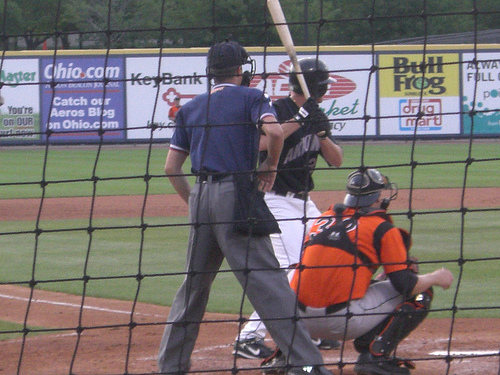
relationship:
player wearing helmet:
[235, 59, 345, 360] [292, 64, 338, 90]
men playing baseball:
[147, 42, 443, 374] [7, 137, 499, 371]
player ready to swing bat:
[235, 59, 345, 360] [268, 3, 324, 116]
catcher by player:
[304, 169, 446, 359] [235, 59, 345, 360]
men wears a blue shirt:
[154, 42, 333, 375] [167, 89, 277, 172]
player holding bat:
[235, 59, 345, 360] [268, 3, 324, 116]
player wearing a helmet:
[235, 59, 345, 360] [292, 64, 338, 90]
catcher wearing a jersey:
[304, 169, 446, 359] [296, 204, 411, 299]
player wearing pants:
[235, 59, 345, 360] [233, 187, 337, 338]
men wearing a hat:
[154, 42, 333, 375] [210, 46, 249, 74]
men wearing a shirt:
[154, 42, 333, 375] [167, 89, 277, 172]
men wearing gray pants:
[154, 42, 333, 375] [157, 175, 320, 372]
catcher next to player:
[304, 169, 446, 359] [235, 59, 345, 360]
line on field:
[7, 284, 165, 331] [2, 46, 498, 374]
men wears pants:
[154, 42, 333, 375] [157, 175, 320, 372]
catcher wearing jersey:
[304, 169, 446, 359] [296, 204, 411, 299]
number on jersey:
[308, 217, 356, 245] [296, 204, 411, 299]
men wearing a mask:
[154, 42, 333, 375] [237, 52, 256, 87]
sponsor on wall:
[42, 61, 123, 91] [7, 58, 496, 140]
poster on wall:
[129, 60, 376, 137] [7, 58, 496, 140]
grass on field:
[21, 142, 490, 183] [2, 46, 498, 374]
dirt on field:
[21, 191, 178, 222] [2, 46, 498, 374]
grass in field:
[21, 142, 490, 183] [2, 46, 498, 374]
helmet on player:
[292, 64, 338, 90] [235, 59, 345, 360]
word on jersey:
[288, 137, 319, 168] [268, 99, 331, 194]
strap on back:
[323, 217, 351, 241] [305, 210, 370, 307]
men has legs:
[154, 42, 333, 375] [160, 225, 320, 371]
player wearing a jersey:
[235, 59, 345, 360] [268, 99, 331, 194]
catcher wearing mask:
[304, 169, 446, 359] [368, 174, 401, 216]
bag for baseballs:
[232, 181, 290, 231] [258, 217, 262, 221]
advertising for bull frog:
[380, 55, 457, 102] [394, 60, 446, 95]